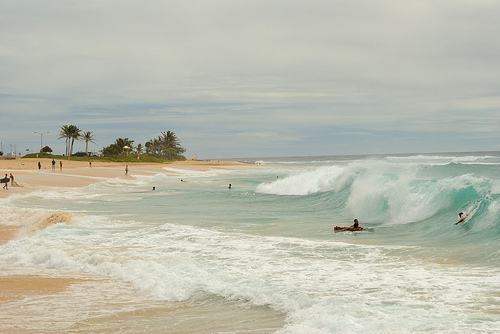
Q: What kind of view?
A: Tropical.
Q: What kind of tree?
A: Palm.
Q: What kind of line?
A: Coastline.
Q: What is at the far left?
A: Trees.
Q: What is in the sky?
A: Clouds.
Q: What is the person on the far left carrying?
A: A surfboard.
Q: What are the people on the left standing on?
A: Sand.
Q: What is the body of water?
A: The ocean.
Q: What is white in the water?
A: Waves.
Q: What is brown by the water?
A: The beach.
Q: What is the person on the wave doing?
A: Surfing.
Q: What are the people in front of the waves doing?
A: Swimming.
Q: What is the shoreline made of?
A: Sand.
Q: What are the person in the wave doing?
A: Surfing.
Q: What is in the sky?
A: Clouds.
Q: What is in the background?
A: Trees.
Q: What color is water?
A: Blue.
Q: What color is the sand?
A: Brown.